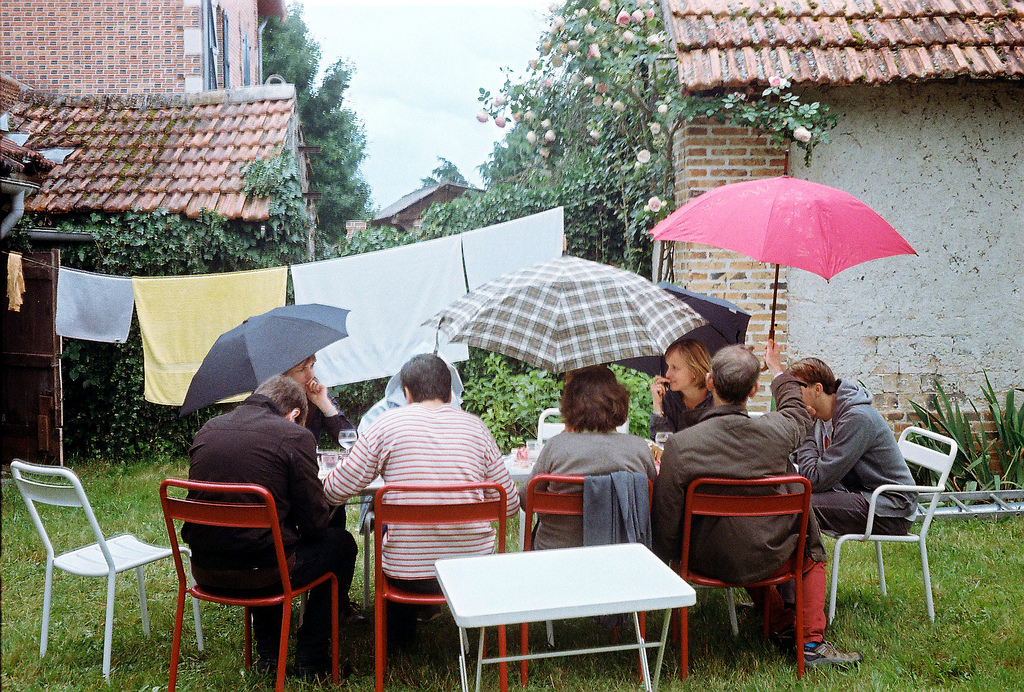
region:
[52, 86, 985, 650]
this is a group of people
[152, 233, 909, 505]
the people are sitting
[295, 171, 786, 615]
the people are gathered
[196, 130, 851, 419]
these are umbrellas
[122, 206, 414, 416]
the umbrella is black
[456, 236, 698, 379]
this umbrella is plaid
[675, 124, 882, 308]
this umbrella is pink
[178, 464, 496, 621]
the chairs are red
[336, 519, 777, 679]
the table is white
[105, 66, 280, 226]
the roof top is brown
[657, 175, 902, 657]
Man holding red umbrella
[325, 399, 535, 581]
Man wearing striped shirt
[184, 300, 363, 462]
Woman holding black umbrella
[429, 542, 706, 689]
White table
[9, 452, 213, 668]
White empty chair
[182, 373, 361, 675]
Man wearing black jacket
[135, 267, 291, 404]
Yellow towel hanging on the clothesline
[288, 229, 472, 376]
White towel hanging on the clothesline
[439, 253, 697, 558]
Woman holding checkered umbrella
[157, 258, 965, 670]
people sitting around a table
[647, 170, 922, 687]
man holding an umbrella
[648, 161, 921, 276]
the umbrella is red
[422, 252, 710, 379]
umbrella has plaid pattern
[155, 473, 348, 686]
the chair is red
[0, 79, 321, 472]
house with terracotta roof tiles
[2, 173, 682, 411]
towel hanging on clothesline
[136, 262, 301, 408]
yellow towel on clothesline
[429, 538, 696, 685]
white table behind people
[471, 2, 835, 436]
flowers next to house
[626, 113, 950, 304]
pink umbrella over people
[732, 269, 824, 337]
handle of the umbrella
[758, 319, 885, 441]
head of the person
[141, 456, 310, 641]
back of the chair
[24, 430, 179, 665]
white chair on ground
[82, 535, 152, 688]
leg on the chair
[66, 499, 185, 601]
seat on the chair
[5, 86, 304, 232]
roof of the building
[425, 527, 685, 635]
white table behind chairs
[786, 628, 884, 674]
brown shoes with blue trim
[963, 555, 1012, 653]
green grass in the yard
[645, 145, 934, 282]
small open pink umbrella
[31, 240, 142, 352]
blue towel on the line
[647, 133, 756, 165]
red and white bricks on the wall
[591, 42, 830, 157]
delicate pink flowers creeping on the wall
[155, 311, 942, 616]
people sitting at the table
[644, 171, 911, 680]
man in a red chair and pink umbrella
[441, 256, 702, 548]
lady in a red chair and plaid umbrella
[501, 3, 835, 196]
pink roses on the side of a building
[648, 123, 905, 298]
open red umbrella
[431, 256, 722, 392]
open brown and white checked umbrella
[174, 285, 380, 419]
open black umbrella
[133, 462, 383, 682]
red metal chair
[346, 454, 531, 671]
red metal chair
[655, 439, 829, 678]
red metal chair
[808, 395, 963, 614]
white metal chair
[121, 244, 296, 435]
yellow towel hanging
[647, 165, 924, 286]
red umbrella held by man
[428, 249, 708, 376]
plaid umbrella held by woman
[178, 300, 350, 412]
black umbrella held by woman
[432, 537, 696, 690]
white table behind the people